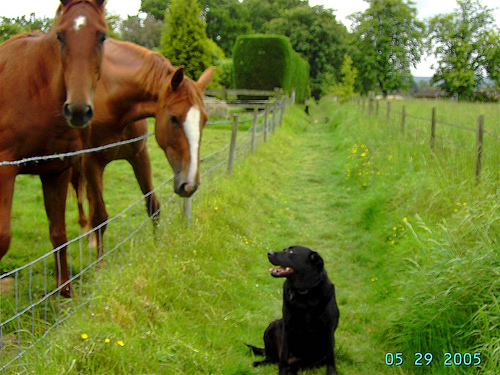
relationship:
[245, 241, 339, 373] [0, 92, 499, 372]
dog on grass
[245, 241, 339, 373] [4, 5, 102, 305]
dog looking at horse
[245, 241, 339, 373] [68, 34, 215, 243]
dog looking at horse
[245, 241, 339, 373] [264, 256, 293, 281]
dog opening h mouth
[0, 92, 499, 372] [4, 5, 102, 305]
grass near horse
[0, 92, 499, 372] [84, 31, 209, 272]
grass near horse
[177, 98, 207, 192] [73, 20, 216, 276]
spot on face of horse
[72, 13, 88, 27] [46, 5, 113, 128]
spot on h head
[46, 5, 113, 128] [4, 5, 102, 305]
head of horse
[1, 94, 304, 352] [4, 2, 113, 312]
fence near horse